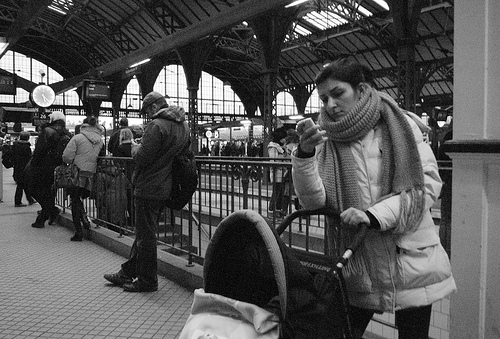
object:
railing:
[200, 163, 262, 209]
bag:
[52, 163, 89, 187]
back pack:
[168, 150, 198, 210]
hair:
[313, 57, 382, 100]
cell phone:
[296, 117, 326, 147]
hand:
[295, 120, 329, 152]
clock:
[33, 85, 56, 108]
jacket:
[289, 128, 457, 313]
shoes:
[103, 268, 158, 292]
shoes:
[70, 215, 91, 242]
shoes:
[30, 209, 62, 229]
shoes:
[14, 200, 38, 208]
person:
[21, 110, 74, 229]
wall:
[87, 156, 140, 205]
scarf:
[317, 82, 431, 279]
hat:
[141, 91, 164, 112]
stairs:
[104, 213, 204, 267]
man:
[103, 90, 191, 293]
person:
[290, 58, 458, 338]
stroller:
[178, 207, 370, 339]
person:
[62, 117, 105, 242]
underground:
[171, 221, 209, 262]